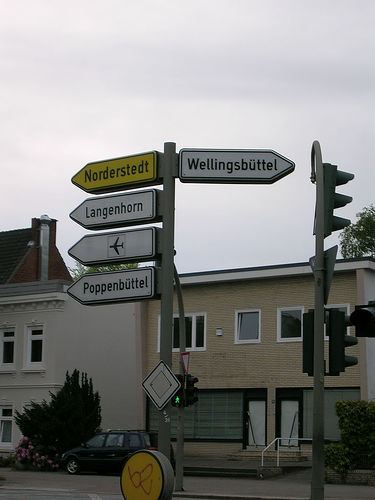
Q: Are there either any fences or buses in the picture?
A: No, there are no fences or buses.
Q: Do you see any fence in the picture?
A: No, there are no fences.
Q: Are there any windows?
A: Yes, there is a window.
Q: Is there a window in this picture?
A: Yes, there is a window.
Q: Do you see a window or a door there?
A: Yes, there is a window.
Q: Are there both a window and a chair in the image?
A: No, there is a window but no chairs.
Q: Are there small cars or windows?
A: Yes, there is a small window.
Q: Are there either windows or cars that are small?
A: Yes, the window is small.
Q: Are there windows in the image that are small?
A: Yes, there is a small window.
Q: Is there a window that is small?
A: Yes, there is a window that is small.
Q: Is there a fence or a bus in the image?
A: No, there are no fences or buses.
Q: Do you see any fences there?
A: No, there are no fences.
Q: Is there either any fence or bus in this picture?
A: No, there are no fences or buses.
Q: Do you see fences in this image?
A: No, there are no fences.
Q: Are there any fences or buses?
A: No, there are no fences or buses.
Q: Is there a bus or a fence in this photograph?
A: No, there are no fences or buses.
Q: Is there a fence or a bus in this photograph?
A: No, there are no fences or buses.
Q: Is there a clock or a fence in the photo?
A: No, there are no fences or clocks.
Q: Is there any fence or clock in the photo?
A: No, there are no fences or clocks.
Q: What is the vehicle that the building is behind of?
A: The vehicle is a car.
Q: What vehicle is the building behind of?
A: The building is behind the car.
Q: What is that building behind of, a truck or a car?
A: The building is behind a car.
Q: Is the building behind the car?
A: Yes, the building is behind the car.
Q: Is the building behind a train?
A: No, the building is behind the car.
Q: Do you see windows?
A: Yes, there is a window.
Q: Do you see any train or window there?
A: Yes, there is a window.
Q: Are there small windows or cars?
A: Yes, there is a small window.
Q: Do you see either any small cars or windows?
A: Yes, there is a small window.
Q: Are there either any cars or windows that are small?
A: Yes, the window is small.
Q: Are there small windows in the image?
A: Yes, there is a small window.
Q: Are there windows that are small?
A: Yes, there is a window that is small.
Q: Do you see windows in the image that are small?
A: Yes, there is a window that is small.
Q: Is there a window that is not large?
A: Yes, there is a small window.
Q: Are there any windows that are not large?
A: Yes, there is a small window.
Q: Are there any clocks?
A: No, there are no clocks.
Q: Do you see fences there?
A: No, there are no fences.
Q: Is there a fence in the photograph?
A: No, there are no fences.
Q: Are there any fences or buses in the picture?
A: No, there are no fences or buses.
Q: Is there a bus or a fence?
A: No, there are no fences or buses.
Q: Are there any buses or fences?
A: No, there are no fences or buses.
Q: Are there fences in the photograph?
A: No, there are no fences.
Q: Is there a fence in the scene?
A: No, there are no fences.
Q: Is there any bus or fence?
A: No, there are no fences or buses.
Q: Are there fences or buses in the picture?
A: No, there are no fences or buses.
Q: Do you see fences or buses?
A: No, there are no fences or buses.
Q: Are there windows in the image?
A: Yes, there is a window.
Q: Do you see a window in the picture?
A: Yes, there is a window.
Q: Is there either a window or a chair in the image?
A: Yes, there is a window.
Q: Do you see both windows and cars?
A: Yes, there are both a window and a car.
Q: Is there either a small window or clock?
A: Yes, there is a small window.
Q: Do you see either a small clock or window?
A: Yes, there is a small window.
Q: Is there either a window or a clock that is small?
A: Yes, the window is small.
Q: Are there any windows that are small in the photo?
A: Yes, there is a small window.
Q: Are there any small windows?
A: Yes, there is a small window.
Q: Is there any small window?
A: Yes, there is a small window.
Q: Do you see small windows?
A: Yes, there is a small window.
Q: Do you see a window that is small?
A: Yes, there is a window that is small.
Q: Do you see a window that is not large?
A: Yes, there is a small window.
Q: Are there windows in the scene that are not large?
A: Yes, there is a small window.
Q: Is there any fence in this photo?
A: No, there are no fences.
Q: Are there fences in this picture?
A: No, there are no fences.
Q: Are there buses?
A: No, there are no buses.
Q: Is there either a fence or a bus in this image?
A: No, there are no buses or fences.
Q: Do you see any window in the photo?
A: Yes, there are windows.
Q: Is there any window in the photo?
A: Yes, there are windows.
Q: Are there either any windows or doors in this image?
A: Yes, there are windows.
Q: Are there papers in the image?
A: No, there are no papers.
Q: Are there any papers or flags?
A: No, there are no papers or flags.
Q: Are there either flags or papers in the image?
A: No, there are no papers or flags.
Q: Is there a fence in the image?
A: No, there are no fences.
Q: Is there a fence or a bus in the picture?
A: No, there are no fences or buses.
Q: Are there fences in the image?
A: No, there are no fences.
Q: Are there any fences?
A: No, there are no fences.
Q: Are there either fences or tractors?
A: No, there are no fences or tractors.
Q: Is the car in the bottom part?
A: Yes, the car is in the bottom of the image.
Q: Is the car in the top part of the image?
A: No, the car is in the bottom of the image.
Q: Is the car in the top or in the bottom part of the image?
A: The car is in the bottom of the image.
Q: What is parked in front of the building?
A: The car is parked in front of the building.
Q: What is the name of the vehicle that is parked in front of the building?
A: The vehicle is a car.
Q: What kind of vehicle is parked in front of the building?
A: The vehicle is a car.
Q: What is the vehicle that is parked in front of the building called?
A: The vehicle is a car.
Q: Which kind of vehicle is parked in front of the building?
A: The vehicle is a car.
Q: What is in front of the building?
A: The car is in front of the building.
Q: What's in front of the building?
A: The car is in front of the building.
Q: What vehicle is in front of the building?
A: The vehicle is a car.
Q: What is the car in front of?
A: The car is in front of the building.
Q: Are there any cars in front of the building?
A: Yes, there is a car in front of the building.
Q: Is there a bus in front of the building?
A: No, there is a car in front of the building.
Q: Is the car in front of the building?
A: Yes, the car is in front of the building.